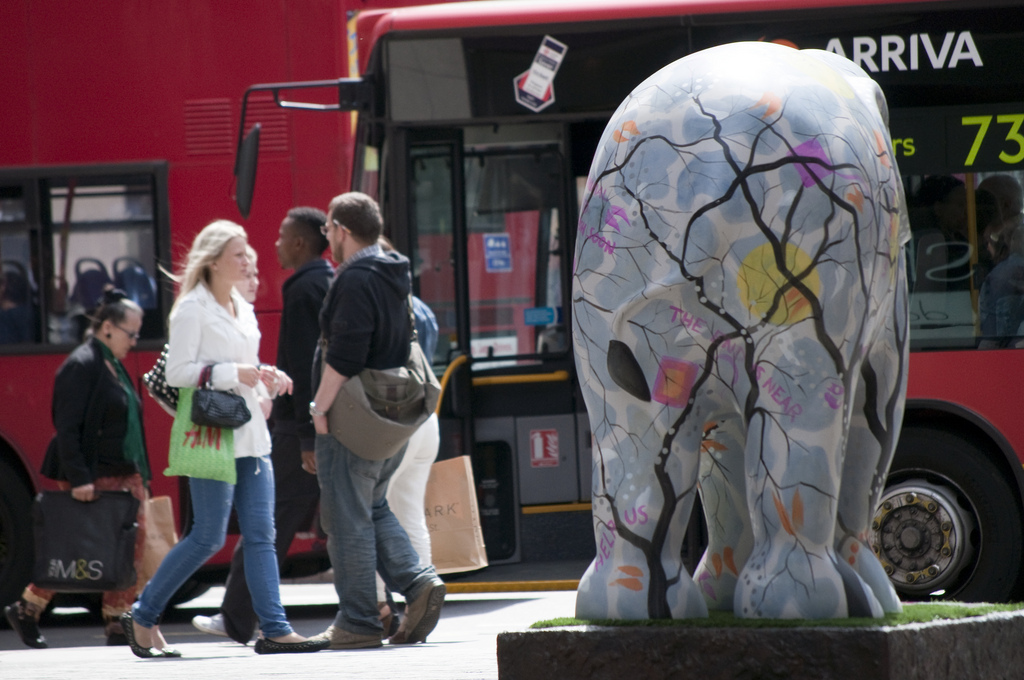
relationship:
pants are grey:
[331, 384, 409, 601] [302, 444, 402, 680]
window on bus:
[374, 133, 604, 389] [326, 10, 1007, 598]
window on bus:
[32, 185, 166, 337] [32, 181, 158, 344]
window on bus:
[2, 196, 61, 356] [2, 10, 433, 561]